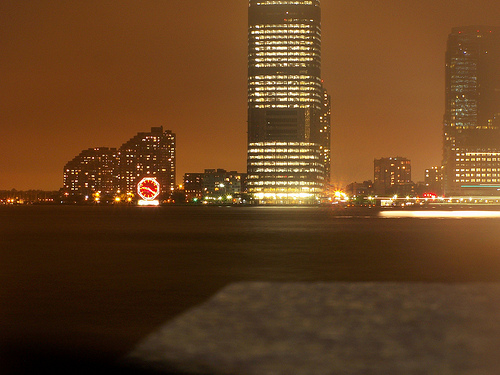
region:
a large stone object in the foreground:
[125, 281, 499, 373]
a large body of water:
[0, 204, 499, 374]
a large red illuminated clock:
[137, 178, 159, 200]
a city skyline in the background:
[0, 0, 499, 207]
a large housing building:
[62, 146, 119, 196]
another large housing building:
[117, 124, 175, 197]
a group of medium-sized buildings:
[182, 167, 245, 199]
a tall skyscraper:
[246, 0, 323, 203]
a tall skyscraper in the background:
[442, 23, 498, 195]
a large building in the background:
[372, 154, 411, 194]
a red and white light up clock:
[134, 177, 161, 203]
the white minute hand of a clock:
[146, 188, 156, 195]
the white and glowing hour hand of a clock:
[140, 185, 149, 192]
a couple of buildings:
[59, 120, 176, 205]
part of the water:
[1, 200, 498, 290]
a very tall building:
[244, 0, 327, 202]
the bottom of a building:
[242, 142, 326, 204]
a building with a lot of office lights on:
[243, 0, 328, 206]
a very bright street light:
[330, 186, 343, 198]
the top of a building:
[121, 120, 178, 157]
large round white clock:
[123, 170, 179, 210]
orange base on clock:
[141, 185, 151, 194]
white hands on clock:
[141, 185, 157, 195]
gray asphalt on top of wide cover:
[244, 292, 379, 332]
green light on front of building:
[457, 180, 492, 190]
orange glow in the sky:
[191, 130, 228, 150]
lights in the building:
[251, 75, 321, 105]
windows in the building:
[460, 151, 490, 177]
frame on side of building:
[178, 165, 190, 190]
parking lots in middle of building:
[259, 106, 304, 138]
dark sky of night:
[5, 4, 459, 181]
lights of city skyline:
[61, 0, 496, 204]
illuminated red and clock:
[136, 175, 162, 205]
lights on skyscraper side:
[249, 2, 321, 202]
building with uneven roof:
[66, 123, 178, 193]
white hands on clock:
[138, 176, 160, 198]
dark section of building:
[248, 100, 316, 155]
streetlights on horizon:
[333, 191, 498, 213]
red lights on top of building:
[447, 21, 499, 41]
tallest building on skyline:
[242, 1, 329, 202]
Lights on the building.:
[238, 21, 309, 107]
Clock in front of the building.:
[128, 175, 161, 213]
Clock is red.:
[131, 168, 183, 210]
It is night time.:
[67, 18, 485, 162]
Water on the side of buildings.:
[81, 192, 348, 289]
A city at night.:
[43, 55, 458, 225]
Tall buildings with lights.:
[226, 5, 334, 229]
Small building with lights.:
[181, 151, 241, 216]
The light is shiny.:
[330, 183, 357, 210]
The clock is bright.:
[135, 177, 160, 217]